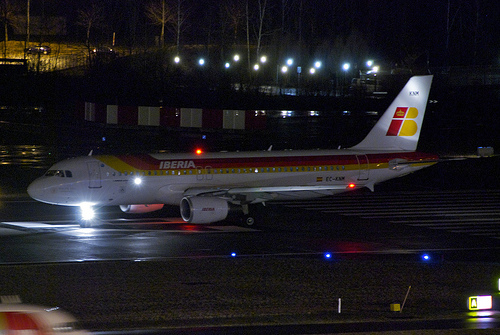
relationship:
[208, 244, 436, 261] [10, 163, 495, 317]
lights on pavement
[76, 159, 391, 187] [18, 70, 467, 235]
side of jet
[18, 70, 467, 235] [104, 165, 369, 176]
plane has windows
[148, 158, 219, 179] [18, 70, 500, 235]
lettering on jet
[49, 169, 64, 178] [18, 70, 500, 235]
pilot on jet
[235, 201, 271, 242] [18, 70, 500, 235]
gear on jet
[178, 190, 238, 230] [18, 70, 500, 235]
engine on jet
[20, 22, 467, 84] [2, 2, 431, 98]
line of trees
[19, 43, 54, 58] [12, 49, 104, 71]
car on street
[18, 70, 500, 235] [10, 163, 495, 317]
jet on pavement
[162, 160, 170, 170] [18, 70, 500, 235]
b on jet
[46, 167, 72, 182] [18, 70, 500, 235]
window on jet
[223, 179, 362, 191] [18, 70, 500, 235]
wing of jet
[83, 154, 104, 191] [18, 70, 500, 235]
door of jet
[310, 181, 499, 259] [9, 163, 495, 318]
lines on pavement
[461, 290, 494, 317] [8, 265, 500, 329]
box on field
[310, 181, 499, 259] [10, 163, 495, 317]
stripes on pavement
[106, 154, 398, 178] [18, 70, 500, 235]
stripes on jet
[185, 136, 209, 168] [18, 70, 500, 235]
light on jet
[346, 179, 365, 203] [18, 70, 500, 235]
light on jet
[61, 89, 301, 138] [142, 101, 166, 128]
building with doors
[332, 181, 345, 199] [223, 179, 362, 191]
edge of wing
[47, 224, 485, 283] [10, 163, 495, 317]
part of pavement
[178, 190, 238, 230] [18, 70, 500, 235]
engine of jet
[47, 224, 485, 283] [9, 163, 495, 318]
part of floor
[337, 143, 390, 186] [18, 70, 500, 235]
part of jet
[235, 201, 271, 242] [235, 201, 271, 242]
gear of gear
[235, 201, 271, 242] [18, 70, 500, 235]
gear of jet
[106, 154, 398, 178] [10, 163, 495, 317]
stripes on pavement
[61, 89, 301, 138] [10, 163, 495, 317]
building near pavement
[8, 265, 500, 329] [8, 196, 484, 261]
grass of courtyard